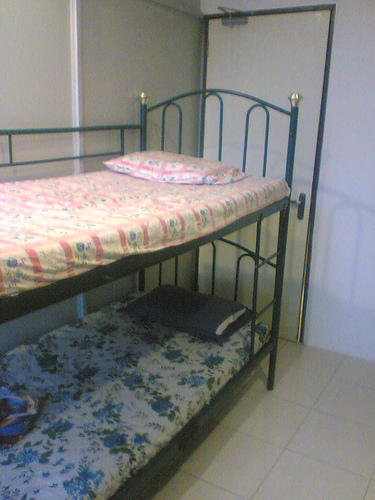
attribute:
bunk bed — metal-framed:
[18, 137, 287, 484]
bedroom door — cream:
[197, 2, 340, 350]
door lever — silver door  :
[267, 184, 314, 231]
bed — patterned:
[7, 91, 315, 264]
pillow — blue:
[114, 282, 258, 344]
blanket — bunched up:
[2, 383, 49, 448]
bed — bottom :
[1, 293, 268, 497]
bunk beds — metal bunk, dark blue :
[79, 205, 260, 396]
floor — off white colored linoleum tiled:
[156, 337, 369, 477]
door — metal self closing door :
[195, 0, 345, 347]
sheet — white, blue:
[0, 153, 289, 293]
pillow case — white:
[105, 143, 245, 189]